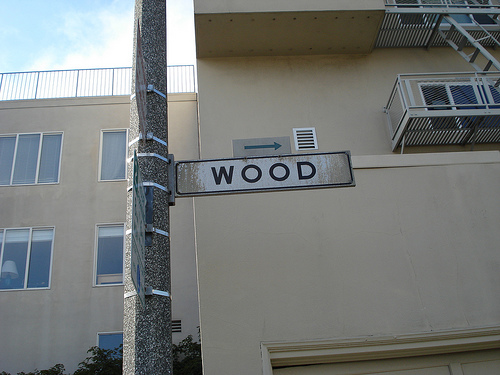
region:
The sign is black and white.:
[178, 145, 358, 192]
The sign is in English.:
[176, 148, 358, 198]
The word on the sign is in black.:
[176, 150, 360, 195]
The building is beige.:
[206, 233, 341, 321]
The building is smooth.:
[225, 222, 390, 317]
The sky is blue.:
[10, 5, 80, 45]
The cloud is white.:
[78, 36, 137, 63]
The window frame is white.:
[1, 223, 60, 290]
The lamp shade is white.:
[1, 256, 19, 277]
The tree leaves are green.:
[73, 343, 120, 370]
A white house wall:
[262, 250, 436, 332]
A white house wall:
[440, 157, 498, 322]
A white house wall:
[214, 68, 364, 119]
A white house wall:
[5, 299, 73, 348]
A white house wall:
[20, 184, 141, 229]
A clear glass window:
[3, 229, 52, 298]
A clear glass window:
[93, 217, 122, 296]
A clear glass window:
[100, 121, 133, 188]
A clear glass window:
[8, 132, 66, 189]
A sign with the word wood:
[176, 157, 355, 197]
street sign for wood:
[180, 159, 318, 186]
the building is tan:
[254, 223, 387, 296]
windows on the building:
[0, 185, 114, 296]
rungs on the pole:
[137, 77, 172, 297]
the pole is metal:
[121, 303, 162, 370]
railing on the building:
[377, 73, 487, 145]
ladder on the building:
[442, 31, 498, 73]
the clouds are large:
[64, 48, 132, 63]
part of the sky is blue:
[6, 8, 93, 55]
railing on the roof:
[43, 63, 130, 94]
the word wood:
[208, 162, 323, 186]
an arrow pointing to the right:
[245, 142, 283, 149]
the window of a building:
[98, 125, 129, 182]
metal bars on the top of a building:
[3, 71, 118, 93]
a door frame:
[261, 343, 493, 361]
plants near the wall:
[81, 348, 121, 374]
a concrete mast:
[126, 300, 173, 372]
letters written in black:
[210, 163, 318, 185]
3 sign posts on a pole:
[127, 20, 284, 287]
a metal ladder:
[442, 20, 494, 65]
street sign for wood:
[175, 129, 343, 201]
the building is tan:
[314, 273, 420, 323]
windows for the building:
[5, 186, 114, 284]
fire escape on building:
[349, 65, 479, 145]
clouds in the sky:
[50, 22, 114, 67]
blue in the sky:
[5, 10, 47, 50]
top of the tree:
[166, 335, 206, 374]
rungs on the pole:
[137, 92, 163, 197]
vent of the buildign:
[290, 114, 327, 151]